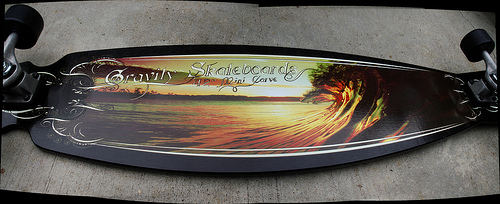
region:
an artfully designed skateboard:
[6, 13, 498, 163]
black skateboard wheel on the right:
[437, 17, 499, 123]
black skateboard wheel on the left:
[3, 1, 85, 143]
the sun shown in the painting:
[250, 56, 309, 88]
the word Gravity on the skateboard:
[84, 55, 184, 99]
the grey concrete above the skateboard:
[38, 0, 433, 50]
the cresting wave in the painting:
[301, 49, 446, 179]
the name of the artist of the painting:
[182, 72, 304, 110]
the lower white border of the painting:
[44, 118, 456, 158]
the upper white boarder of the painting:
[61, 33, 433, 81]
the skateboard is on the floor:
[11, 18, 497, 146]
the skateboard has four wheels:
[20, 17, 497, 130]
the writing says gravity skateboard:
[111, 60, 315, 122]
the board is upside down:
[30, 20, 497, 157]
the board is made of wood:
[32, 43, 484, 162]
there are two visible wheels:
[8, 9, 492, 139]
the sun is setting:
[202, 68, 317, 118]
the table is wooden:
[105, 175, 456, 193]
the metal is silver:
[10, 34, 34, 98]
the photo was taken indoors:
[14, 29, 499, 175]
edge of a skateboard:
[271, 139, 349, 182]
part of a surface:
[394, 163, 436, 198]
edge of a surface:
[479, 191, 495, 201]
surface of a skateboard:
[310, 92, 397, 133]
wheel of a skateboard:
[456, 15, 482, 57]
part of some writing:
[228, 53, 313, 99]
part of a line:
[186, 47, 212, 59]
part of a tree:
[306, 65, 348, 85]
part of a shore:
[206, 123, 274, 138]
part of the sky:
[273, 85, 298, 95]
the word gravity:
[87, 51, 179, 99]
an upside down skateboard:
[5, 11, 490, 163]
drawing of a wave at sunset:
[239, 62, 429, 149]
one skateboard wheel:
[462, 8, 498, 78]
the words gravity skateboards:
[96, 54, 316, 105]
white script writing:
[104, 61, 330, 111]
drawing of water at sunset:
[115, 96, 345, 151]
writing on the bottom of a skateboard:
[100, 54, 323, 102]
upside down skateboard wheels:
[451, 24, 498, 138]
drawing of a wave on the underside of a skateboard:
[304, 55, 430, 142]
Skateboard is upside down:
[1, 1, 496, 173]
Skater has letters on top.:
[100, 53, 322, 88]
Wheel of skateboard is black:
[450, 24, 497, 65]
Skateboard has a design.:
[70, 48, 433, 149]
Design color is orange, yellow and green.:
[71, 51, 386, 153]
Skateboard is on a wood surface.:
[2, 5, 492, 201]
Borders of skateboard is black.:
[32, 38, 477, 180]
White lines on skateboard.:
[78, 131, 450, 161]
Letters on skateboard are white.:
[99, 57, 321, 99]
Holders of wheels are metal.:
[3, 31, 26, 70]